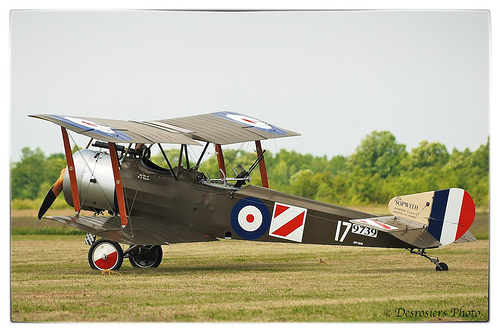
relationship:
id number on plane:
[334, 214, 380, 248] [44, 111, 496, 273]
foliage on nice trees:
[325, 185, 392, 202] [318, 126, 438, 181]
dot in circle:
[244, 212, 254, 222] [227, 197, 270, 239]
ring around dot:
[239, 205, 263, 231] [240, 213, 263, 236]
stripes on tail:
[430, 185, 477, 248] [348, 187, 480, 254]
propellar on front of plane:
[34, 141, 86, 223] [44, 111, 496, 273]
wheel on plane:
[430, 261, 454, 276] [44, 111, 496, 273]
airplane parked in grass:
[25, 110, 475, 272] [13, 225, 487, 319]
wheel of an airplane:
[87, 237, 120, 272] [27, 93, 479, 278]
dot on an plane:
[245, 214, 254, 223] [20, 92, 468, 284]